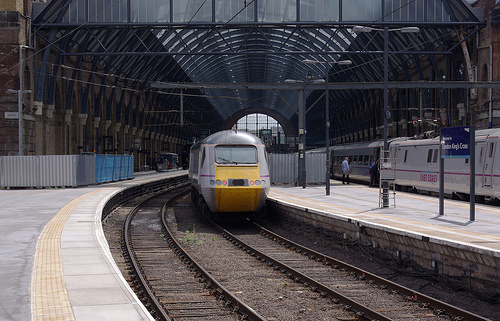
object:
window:
[229, 113, 286, 145]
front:
[215, 162, 262, 213]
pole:
[325, 63, 330, 196]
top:
[203, 129, 265, 144]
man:
[342, 157, 351, 186]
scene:
[0, 24, 498, 270]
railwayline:
[152, 236, 357, 315]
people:
[163, 159, 169, 171]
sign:
[440, 126, 471, 158]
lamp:
[300, 59, 352, 66]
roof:
[146, 23, 360, 122]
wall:
[24, 154, 78, 189]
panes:
[215, 26, 299, 63]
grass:
[302, 184, 326, 201]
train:
[189, 128, 272, 213]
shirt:
[341, 160, 350, 171]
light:
[250, 180, 266, 186]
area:
[2, 187, 105, 267]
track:
[120, 181, 265, 321]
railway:
[198, 214, 284, 259]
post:
[297, 89, 306, 188]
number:
[208, 160, 274, 185]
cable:
[183, 87, 229, 113]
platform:
[0, 188, 110, 249]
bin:
[369, 158, 394, 188]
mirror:
[261, 130, 271, 134]